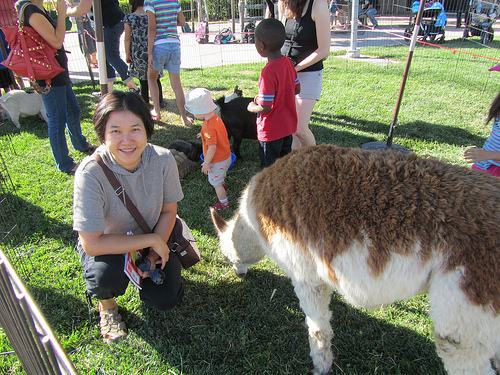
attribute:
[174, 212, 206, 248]
bag — brown, leather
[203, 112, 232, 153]
shirt — orange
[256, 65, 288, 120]
shirt — red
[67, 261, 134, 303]
short — jean, green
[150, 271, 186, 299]
pant — jean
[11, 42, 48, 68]
bag — red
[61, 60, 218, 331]
woman — posing, wearing, carrying, kneeling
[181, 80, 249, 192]
boy — little, young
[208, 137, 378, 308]
llama — white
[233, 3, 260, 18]
fence — wired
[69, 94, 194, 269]
person — wearing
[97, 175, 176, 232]
shirt — gray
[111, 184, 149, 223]
strap — leather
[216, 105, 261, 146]
stroller — black, background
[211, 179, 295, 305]
animal — eating, white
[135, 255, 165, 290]
sunglasses — black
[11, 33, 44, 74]
purse — red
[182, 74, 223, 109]
hat — white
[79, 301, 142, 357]
shoe — athletic